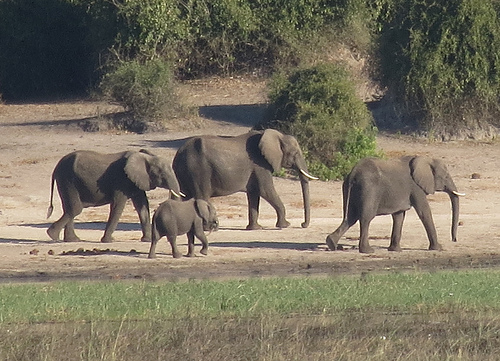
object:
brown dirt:
[3, 79, 498, 269]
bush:
[266, 56, 378, 181]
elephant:
[326, 157, 465, 254]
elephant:
[172, 128, 319, 230]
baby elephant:
[148, 198, 220, 260]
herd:
[46, 129, 467, 258]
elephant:
[46, 149, 185, 243]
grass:
[4, 265, 499, 357]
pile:
[28, 248, 139, 256]